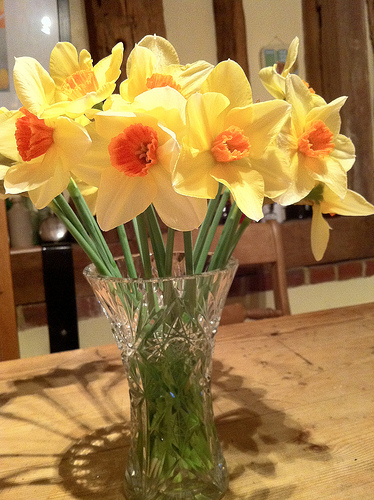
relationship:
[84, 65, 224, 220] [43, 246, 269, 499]
flower in vase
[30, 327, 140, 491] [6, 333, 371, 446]
shadow on table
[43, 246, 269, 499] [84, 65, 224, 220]
vase with flower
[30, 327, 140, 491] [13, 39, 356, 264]
shadow of boquet